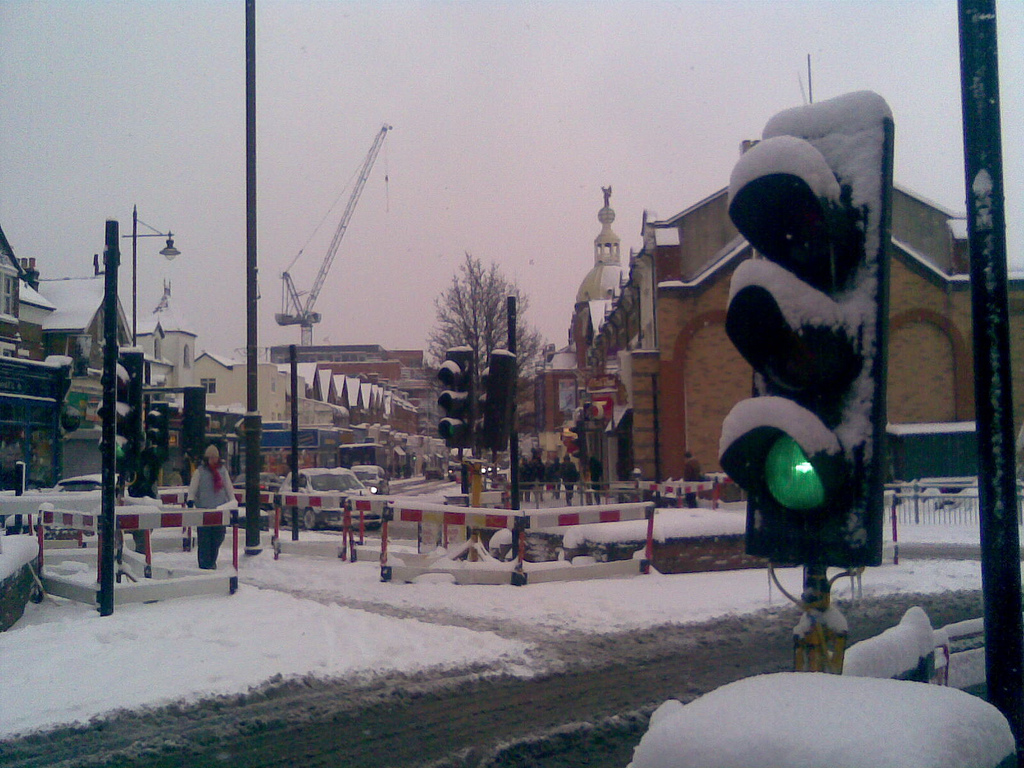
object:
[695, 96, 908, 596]
traffic signal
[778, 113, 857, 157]
snow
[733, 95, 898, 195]
snow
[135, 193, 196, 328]
street light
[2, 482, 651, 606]
barriers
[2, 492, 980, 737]
sidewalk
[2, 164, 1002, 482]
buildings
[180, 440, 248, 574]
person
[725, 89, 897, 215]
snow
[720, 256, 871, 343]
snow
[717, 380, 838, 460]
snow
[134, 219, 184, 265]
lamp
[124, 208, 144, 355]
post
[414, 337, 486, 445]
traffic signal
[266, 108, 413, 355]
crane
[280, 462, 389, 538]
car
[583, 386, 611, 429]
flag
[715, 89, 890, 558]
light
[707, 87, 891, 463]
snow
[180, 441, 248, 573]
woman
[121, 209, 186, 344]
light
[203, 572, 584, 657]
pathway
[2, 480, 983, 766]
snow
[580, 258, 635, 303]
dome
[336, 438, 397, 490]
bus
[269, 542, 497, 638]
road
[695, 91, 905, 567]
light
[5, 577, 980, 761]
road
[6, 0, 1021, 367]
sky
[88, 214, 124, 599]
pole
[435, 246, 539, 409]
tree